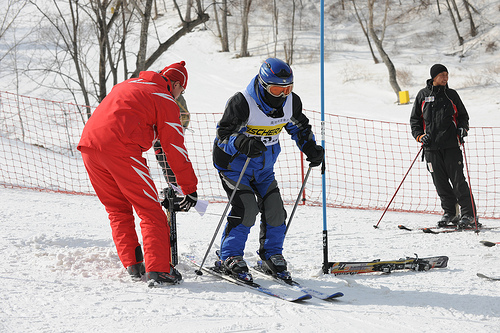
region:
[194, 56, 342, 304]
Person on skis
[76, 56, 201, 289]
Man leaning over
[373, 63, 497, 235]
Man on skis smiling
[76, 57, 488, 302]
Three men getting ready to ski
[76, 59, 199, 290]
Men wearing orange winter gear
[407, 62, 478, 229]
Man in a black cap wearing black winter clothing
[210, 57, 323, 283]
Man wearing blue and black ski gear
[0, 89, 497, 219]
Red net fencing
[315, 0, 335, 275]
Tall blue pole with black base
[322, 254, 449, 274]
Pair of skis lying on the ground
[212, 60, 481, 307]
two men wearing skis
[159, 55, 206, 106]
a man wearing a red and white hat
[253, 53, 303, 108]
a man wearing a helmet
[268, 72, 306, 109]
a man wearing goggles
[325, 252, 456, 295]
a snow ski on the ground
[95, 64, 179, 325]
a man wearing a red suit with white stripe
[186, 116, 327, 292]
a man holding ski poles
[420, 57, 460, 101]
a man wearing a black hat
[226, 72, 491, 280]
two men holding ski poles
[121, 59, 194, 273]
a man bent over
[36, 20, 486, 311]
The people are preparing to ski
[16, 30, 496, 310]
The people are in a ski area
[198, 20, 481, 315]
The people are wearing snow skis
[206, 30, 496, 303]
The people are wearing warm clothes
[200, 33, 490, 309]
The people are enjoying their day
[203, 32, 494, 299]
The people are enjoying the mountain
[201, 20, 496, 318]
The people are testing their skill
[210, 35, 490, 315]
The people are running a race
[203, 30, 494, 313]
The people are holding ski poles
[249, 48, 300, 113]
A person is wearing a helmet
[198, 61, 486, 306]
Two people are skiing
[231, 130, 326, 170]
A pair of black gloves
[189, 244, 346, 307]
Two skis under feet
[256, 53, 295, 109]
A helmet is blue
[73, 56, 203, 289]
Man wearing a red outfit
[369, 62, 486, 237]
A man holding two ski poles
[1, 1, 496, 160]
Many trees in the background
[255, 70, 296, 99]
A pair of goggles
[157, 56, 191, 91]
White stripe on red hat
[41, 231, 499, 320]
Shadows on the snow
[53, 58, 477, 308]
THREE PEOPLE WEARING SKIS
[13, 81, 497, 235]
RED MESH NET BEHIND SKIERS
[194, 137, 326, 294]
SKI POLES IN SKIERS HANDS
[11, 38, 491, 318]
SNOW COVERING WHOLE AREA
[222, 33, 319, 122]
HELMET ON SKIERS HEAD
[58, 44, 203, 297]
SKIER IN ORANGE SKI SUIT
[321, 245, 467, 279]
LONE SKI IN SNOW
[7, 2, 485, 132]
BARE TREES IN BACKGROUND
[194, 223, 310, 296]
SNOW BOOTS ON SKIERS FEET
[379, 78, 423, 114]
UNIDENTIFIED YELLOW OBJECT IN SNOW